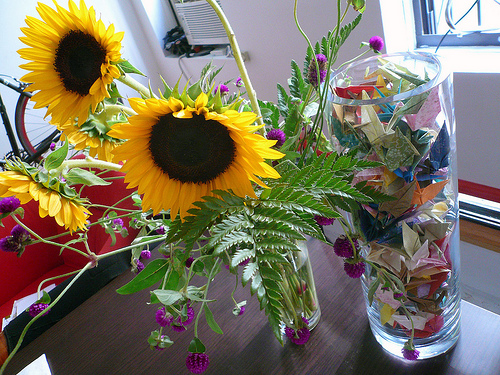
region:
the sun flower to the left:
[0, 147, 95, 240]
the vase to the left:
[236, 182, 332, 344]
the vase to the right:
[315, 25, 475, 362]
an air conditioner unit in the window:
[172, 0, 244, 59]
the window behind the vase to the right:
[406, 5, 498, 52]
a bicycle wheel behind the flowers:
[10, 73, 90, 165]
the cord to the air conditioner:
[172, 45, 196, 87]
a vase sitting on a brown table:
[317, 35, 469, 369]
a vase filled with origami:
[320, 40, 483, 368]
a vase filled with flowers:
[222, 128, 328, 353]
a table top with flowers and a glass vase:
[6, 5, 491, 366]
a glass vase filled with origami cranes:
[325, 53, 465, 368]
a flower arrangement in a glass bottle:
[4, 1, 326, 351]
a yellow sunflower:
[107, 97, 284, 221]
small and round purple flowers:
[148, 293, 214, 374]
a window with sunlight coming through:
[407, 3, 498, 51]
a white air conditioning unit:
[156, 2, 235, 56]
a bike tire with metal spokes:
[3, 86, 55, 155]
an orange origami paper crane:
[412, 173, 449, 207]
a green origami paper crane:
[386, 127, 418, 174]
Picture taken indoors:
[17, 26, 484, 345]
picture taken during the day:
[18, 24, 497, 321]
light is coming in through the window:
[409, 17, 493, 62]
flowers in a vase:
[23, 26, 320, 361]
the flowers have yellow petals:
[116, 105, 329, 266]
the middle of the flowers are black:
[163, 136, 237, 171]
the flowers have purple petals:
[146, 301, 253, 374]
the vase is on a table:
[238, 271, 368, 371]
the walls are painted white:
[262, 31, 278, 67]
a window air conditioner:
[176, 7, 281, 86]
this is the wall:
[251, 9, 276, 36]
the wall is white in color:
[251, 13, 269, 44]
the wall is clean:
[245, 6, 278, 36]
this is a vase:
[327, 51, 473, 351]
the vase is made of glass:
[371, 324, 457, 355]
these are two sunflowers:
[16, 5, 282, 207]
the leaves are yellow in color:
[124, 130, 139, 153]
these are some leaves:
[226, 201, 287, 298]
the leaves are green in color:
[232, 205, 269, 254]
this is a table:
[78, 310, 143, 373]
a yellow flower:
[121, 106, 263, 204]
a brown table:
[84, 310, 148, 370]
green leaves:
[280, 154, 347, 221]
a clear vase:
[283, 263, 333, 329]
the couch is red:
[10, 255, 73, 297]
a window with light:
[422, 2, 493, 37]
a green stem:
[228, 32, 249, 102]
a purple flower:
[187, 350, 207, 368]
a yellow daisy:
[32, 17, 117, 125]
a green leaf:
[116, 277, 178, 296]